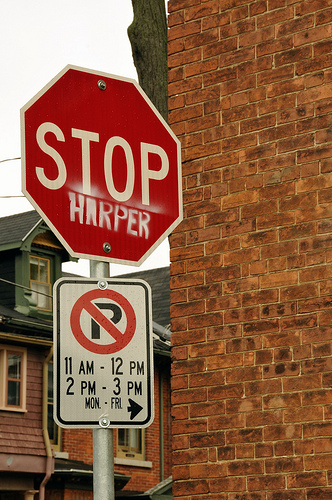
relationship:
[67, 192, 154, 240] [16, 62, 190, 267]
graffiti written on stop sign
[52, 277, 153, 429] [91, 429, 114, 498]
sign on pole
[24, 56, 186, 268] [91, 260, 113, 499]
sign on a pole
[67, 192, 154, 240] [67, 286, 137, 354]
graffiti on a letter p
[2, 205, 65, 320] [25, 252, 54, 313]
attic has window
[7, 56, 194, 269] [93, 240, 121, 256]
sign has bolts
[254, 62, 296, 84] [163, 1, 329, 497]
brick on building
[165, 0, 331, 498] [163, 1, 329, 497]
brick on building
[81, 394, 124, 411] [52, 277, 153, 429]
lettering on sign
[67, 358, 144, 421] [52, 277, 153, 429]
hours are on sign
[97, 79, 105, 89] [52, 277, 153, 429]
screw on sign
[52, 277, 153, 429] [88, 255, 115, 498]
sign attached to pipe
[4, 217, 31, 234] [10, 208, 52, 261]
shingles are on house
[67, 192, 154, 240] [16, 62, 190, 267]
graffiti on stop sign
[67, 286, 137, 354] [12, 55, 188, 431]
letter p on sign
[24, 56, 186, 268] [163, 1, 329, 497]
sign next to building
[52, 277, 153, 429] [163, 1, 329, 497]
sign next to building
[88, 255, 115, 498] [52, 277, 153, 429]
pipe holding sign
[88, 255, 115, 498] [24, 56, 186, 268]
pipe holding sign